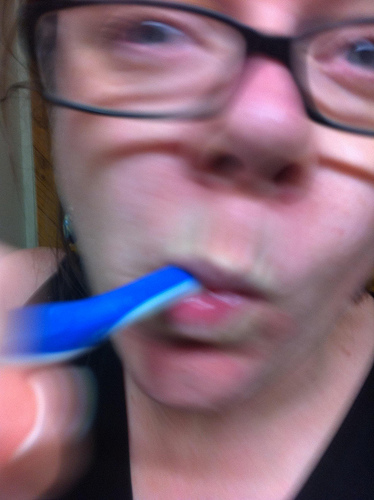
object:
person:
[1, 1, 373, 500]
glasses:
[25, 0, 373, 138]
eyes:
[109, 13, 204, 56]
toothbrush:
[1, 265, 203, 368]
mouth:
[149, 255, 264, 327]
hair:
[0, 0, 90, 302]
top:
[4, 251, 373, 499]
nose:
[194, 41, 316, 193]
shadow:
[64, 79, 373, 187]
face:
[52, 0, 373, 407]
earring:
[61, 216, 74, 244]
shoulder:
[1, 242, 68, 307]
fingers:
[1, 364, 94, 443]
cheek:
[55, 118, 174, 231]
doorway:
[17, 2, 78, 251]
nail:
[10, 367, 95, 459]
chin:
[112, 329, 292, 408]